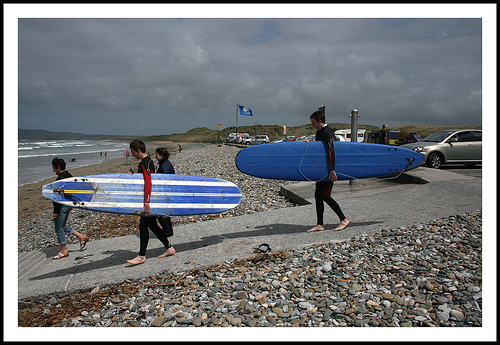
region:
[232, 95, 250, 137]
The blue flag on the pole.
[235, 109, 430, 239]
The guy holding a blue surfboard.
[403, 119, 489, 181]
The parked silver car.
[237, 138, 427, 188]
The long blue surfboard.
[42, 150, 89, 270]
Woman in jeans walking.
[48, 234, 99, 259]
The silver sandals.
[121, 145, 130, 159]
Person wearing red.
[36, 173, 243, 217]
The blue and white surfboard.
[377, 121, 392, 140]
Man standing.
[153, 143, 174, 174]
Woman with a blue shirt.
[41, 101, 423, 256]
people carrying surfboards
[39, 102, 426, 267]
people going surfing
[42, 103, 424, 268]
people carrying two blue surfboards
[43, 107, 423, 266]
people on there way to go surfing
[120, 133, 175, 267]
boy carrying a surfboard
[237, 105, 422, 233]
girl carrying a surfboard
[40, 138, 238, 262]
boy carrying a blue and white surfboard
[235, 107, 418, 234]
girl carrying a blue surfboard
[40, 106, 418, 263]
people walking down a walk way carrying surfboards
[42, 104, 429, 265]
people on there way to go surfing in the water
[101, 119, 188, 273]
surfer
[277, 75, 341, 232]
surfer with blue board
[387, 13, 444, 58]
white clouds in blue sky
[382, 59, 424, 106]
white clouds in blue sky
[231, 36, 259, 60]
white clouds in blue sky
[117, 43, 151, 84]
white clouds in blue sky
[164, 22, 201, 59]
white clouds in blue sky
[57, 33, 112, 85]
white clouds in blue sky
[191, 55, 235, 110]
white clouds in blue sky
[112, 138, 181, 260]
man carrying a surfboard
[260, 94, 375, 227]
man carrying a surboard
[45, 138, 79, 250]
the man is walking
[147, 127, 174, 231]
the woman is walking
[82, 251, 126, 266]
shadow of the man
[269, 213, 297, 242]
shadow of the man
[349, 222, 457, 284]
rocks on the side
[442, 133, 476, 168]
the car is parked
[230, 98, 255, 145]
the flag is blue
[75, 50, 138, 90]
the sky is cloudy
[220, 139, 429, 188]
long blue surf board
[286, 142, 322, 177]
white leash on top of board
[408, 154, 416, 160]
black leash holder on board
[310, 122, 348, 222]
black wet suit on person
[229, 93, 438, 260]
person carrying surf board down ramp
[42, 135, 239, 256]
person carrying surfboard down ramp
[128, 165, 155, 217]
red sleeve of wet suit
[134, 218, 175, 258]
black bottoms of wet suit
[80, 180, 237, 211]
blue and white lines on board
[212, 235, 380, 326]
large pile of rocks